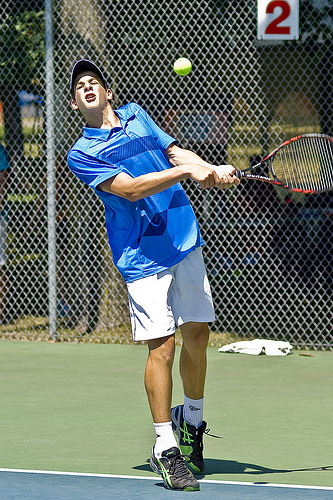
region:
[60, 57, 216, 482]
man playing tennis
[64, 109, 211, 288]
tennis player wearing blue shirt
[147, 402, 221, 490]
tennis player has green and black shoes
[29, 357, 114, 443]
surface of tennis court is green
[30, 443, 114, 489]
part of the tennis court surface is blue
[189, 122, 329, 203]
man holding tennis racket with two hands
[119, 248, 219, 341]
man wearing white shorts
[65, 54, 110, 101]
man looking up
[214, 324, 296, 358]
white cloth lying on the ground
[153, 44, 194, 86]
tennis ball is in mid air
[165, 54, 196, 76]
a yellow ball flying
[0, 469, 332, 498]
a blue tennis court with a white stripe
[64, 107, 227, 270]
a blue shirt on a man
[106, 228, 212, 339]
white shorts on a man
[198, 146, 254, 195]
two hands holding a tennis racquet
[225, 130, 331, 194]
a red and black tennis racquet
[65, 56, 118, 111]
a cap worn by a man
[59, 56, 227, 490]
a man hitting a ball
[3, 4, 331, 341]
a chain link fence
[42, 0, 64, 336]
a round metal post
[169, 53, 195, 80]
a green tennis ball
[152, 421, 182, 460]
a white sock on the man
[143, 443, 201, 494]
a green and gray shoe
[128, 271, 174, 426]
the leg of the man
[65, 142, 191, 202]
the arm of the man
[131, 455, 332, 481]
a shadow on the ground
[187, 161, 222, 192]
the hand of the man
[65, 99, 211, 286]
a blue polo shirt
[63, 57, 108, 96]
a baseball cap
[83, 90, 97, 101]
the mouth of the man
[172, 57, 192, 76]
a yellow tennis ball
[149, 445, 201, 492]
green and black shoe on foot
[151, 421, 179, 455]
white crew sock above shoe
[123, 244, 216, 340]
man wearing white knee length shorts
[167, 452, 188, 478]
black lace on shoe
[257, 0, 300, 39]
number on chain link fence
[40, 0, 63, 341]
tall gray metal fence post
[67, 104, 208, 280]
blue polo shirt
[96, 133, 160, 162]
tonal stripe on shirt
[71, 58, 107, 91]
cap on head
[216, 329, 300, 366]
a white shirt laying on ground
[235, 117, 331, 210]
a black and orange tennis racquet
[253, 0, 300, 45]
a white sign with number two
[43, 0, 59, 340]
a grey metal fence post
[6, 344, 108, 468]
green turf on tennis court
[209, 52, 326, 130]
protective chain fencing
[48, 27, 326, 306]
a man playing tennis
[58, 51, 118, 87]
a black hat visor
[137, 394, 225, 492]
black and green tennis shoes